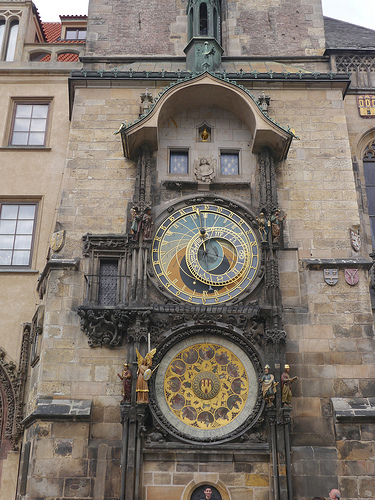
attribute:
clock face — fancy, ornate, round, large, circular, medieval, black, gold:
[153, 201, 249, 290]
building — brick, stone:
[2, 2, 375, 500]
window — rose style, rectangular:
[10, 101, 48, 142]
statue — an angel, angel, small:
[195, 151, 216, 189]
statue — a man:
[261, 364, 283, 411]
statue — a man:
[275, 360, 298, 409]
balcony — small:
[23, 41, 83, 64]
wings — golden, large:
[136, 348, 152, 372]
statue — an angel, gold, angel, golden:
[132, 344, 157, 398]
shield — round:
[145, 368, 153, 380]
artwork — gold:
[164, 343, 247, 428]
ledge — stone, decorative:
[68, 66, 352, 85]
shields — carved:
[320, 266, 360, 288]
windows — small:
[168, 142, 240, 183]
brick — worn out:
[86, 3, 324, 59]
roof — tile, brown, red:
[40, 13, 373, 58]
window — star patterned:
[221, 153, 237, 176]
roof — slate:
[32, 12, 80, 61]